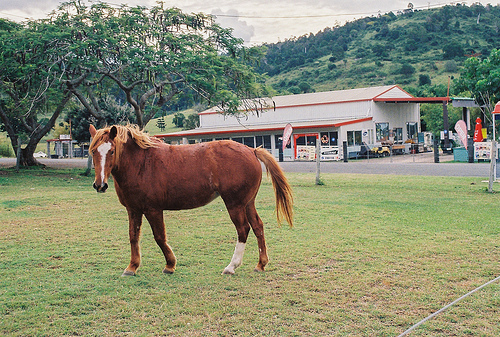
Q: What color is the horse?
A: Brown.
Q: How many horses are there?
A: One.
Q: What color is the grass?
A: Green.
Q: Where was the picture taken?
A: The field.